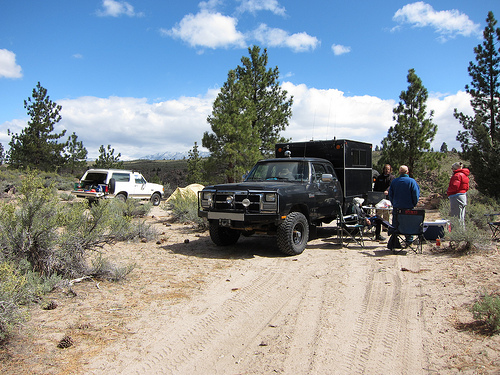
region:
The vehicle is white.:
[73, 157, 173, 217]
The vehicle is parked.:
[58, 159, 179, 246]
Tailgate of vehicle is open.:
[58, 157, 177, 231]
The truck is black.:
[184, 118, 384, 267]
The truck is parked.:
[183, 109, 382, 281]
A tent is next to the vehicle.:
[61, 150, 215, 248]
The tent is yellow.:
[68, 157, 213, 244]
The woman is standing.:
[423, 142, 484, 247]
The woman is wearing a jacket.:
[421, 153, 480, 248]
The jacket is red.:
[433, 153, 487, 222]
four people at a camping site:
[372, 160, 468, 248]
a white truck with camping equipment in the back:
[70, 165, 165, 205]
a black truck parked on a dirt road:
[195, 136, 372, 251]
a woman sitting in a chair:
[347, 195, 392, 252]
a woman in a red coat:
[446, 160, 470, 235]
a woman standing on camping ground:
[447, 161, 470, 235]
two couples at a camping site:
[350, 161, 470, 248]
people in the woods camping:
[2, 11, 497, 364]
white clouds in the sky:
[70, 2, 450, 128]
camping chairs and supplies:
[320, 203, 497, 255]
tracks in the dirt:
[180, 276, 410, 365]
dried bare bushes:
[19, 203, 134, 290]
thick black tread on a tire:
[278, 218, 295, 245]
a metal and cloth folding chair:
[334, 199, 368, 251]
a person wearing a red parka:
[449, 160, 474, 227]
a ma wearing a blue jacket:
[386, 163, 418, 242]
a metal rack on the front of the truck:
[191, 190, 276, 216]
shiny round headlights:
[208, 195, 254, 208]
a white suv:
[76, 158, 168, 214]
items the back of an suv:
[76, 177, 108, 196]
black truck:
[206, 139, 356, 264]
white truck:
[85, 155, 210, 355]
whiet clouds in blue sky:
[11, 6, 126, 74]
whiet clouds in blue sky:
[8, 47, 88, 81]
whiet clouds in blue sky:
[108, 92, 183, 136]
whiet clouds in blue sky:
[125, 15, 193, 66]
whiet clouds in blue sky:
[196, 7, 281, 51]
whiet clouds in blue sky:
[288, 19, 336, 69]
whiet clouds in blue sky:
[321, 47, 388, 97]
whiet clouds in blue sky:
[309, 95, 367, 135]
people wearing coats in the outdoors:
[372, 161, 472, 254]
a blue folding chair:
[393, 208, 426, 252]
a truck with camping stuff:
[198, 138, 373, 255]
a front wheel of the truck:
[277, 210, 308, 253]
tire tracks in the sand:
[155, 271, 433, 364]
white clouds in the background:
[81, 98, 181, 141]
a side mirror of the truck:
[321, 173, 333, 182]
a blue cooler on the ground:
[422, 220, 448, 242]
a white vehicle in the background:
[68, 168, 165, 208]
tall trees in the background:
[204, 42, 283, 150]